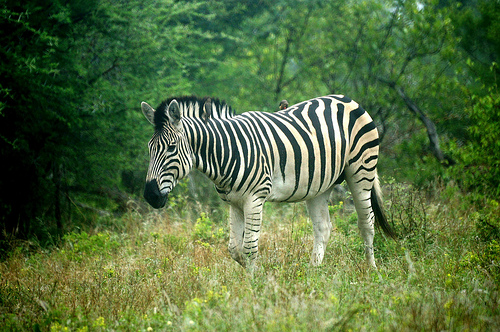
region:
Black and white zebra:
[133, 85, 390, 268]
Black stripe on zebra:
[227, 116, 254, 191]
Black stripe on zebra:
[246, 108, 277, 173]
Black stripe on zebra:
[252, 108, 287, 184]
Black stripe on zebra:
[257, 110, 303, 202]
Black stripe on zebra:
[306, 97, 326, 194]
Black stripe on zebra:
[317, 97, 337, 189]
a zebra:
[131, 86, 407, 263]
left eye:
[166, 142, 179, 154]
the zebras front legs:
[224, 210, 261, 273]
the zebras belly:
[287, 153, 331, 196]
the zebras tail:
[372, 183, 396, 231]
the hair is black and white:
[183, 98, 221, 113]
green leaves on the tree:
[118, 24, 174, 81]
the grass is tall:
[180, 283, 253, 314]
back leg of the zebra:
[300, 199, 336, 260]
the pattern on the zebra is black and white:
[258, 123, 333, 157]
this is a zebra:
[50, 33, 434, 254]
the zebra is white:
[178, 93, 432, 271]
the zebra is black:
[144, 73, 365, 213]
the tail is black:
[360, 178, 420, 269]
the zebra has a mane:
[155, 68, 237, 129]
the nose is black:
[141, 161, 176, 191]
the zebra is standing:
[127, 107, 417, 268]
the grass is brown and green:
[130, 255, 304, 329]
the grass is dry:
[102, 243, 307, 317]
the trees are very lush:
[102, 14, 370, 111]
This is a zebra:
[130, 85, 419, 300]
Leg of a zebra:
[342, 164, 394, 309]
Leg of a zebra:
[307, 191, 335, 277]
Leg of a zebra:
[242, 190, 275, 289]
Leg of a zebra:
[216, 190, 244, 265]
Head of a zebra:
[127, 90, 213, 226]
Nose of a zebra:
[135, 180, 165, 202]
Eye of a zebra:
[164, 138, 180, 155]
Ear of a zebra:
[160, 95, 186, 127]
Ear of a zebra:
[134, 95, 167, 129]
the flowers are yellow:
[148, 225, 212, 258]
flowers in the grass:
[70, 225, 264, 325]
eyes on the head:
[163, 142, 187, 172]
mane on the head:
[152, 105, 173, 149]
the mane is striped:
[173, 102, 233, 132]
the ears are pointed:
[140, 99, 180, 126]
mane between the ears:
[137, 97, 184, 128]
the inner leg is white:
[309, 195, 334, 277]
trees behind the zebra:
[220, 36, 493, 193]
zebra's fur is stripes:
[120, 77, 402, 281]